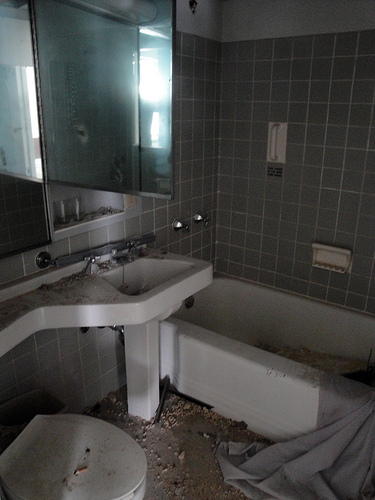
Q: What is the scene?
A: Bathroom.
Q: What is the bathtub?
A: White.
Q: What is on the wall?
A: The mirror.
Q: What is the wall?
A: Tiled.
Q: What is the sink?
A: White.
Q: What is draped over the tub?
A: Grey shower curtain.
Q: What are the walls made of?
A: Tiles.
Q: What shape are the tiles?
A: Square.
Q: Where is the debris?
A: All over the bathroom.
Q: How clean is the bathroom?
A: Very dirty.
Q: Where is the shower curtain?
A: On the tub.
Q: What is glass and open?
A: The mirror.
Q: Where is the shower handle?
A: On the wall.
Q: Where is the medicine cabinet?
A: On the wall.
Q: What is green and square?
A: The tiles.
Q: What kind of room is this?
A: Bathroom.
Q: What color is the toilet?
A: White.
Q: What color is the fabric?
A: Gray.